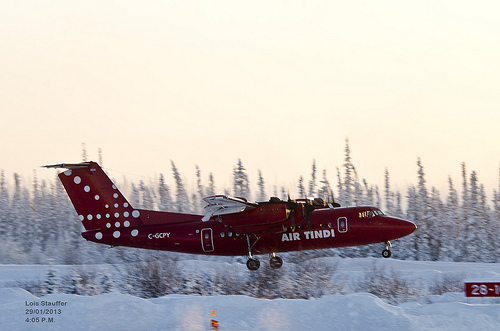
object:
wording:
[281, 229, 336, 243]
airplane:
[42, 162, 417, 269]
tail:
[42, 162, 142, 230]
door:
[200, 229, 212, 253]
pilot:
[366, 211, 373, 221]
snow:
[0, 132, 500, 330]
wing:
[201, 192, 301, 226]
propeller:
[279, 190, 299, 218]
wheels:
[247, 255, 261, 272]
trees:
[459, 157, 500, 259]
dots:
[121, 221, 133, 230]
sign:
[463, 283, 499, 296]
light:
[298, 223, 303, 230]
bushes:
[135, 253, 328, 304]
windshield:
[375, 208, 382, 215]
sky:
[1, 4, 497, 212]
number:
[471, 285, 489, 297]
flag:
[208, 320, 221, 329]